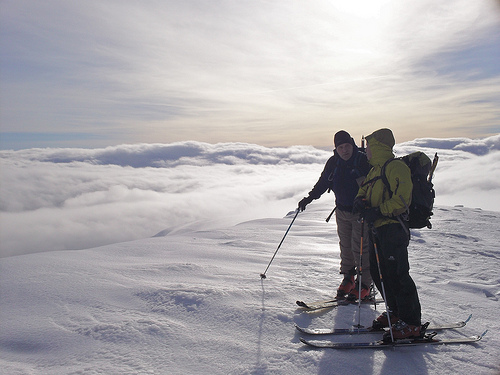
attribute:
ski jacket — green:
[312, 138, 344, 212]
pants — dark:
[366, 269, 419, 375]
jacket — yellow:
[384, 158, 417, 217]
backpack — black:
[421, 151, 432, 229]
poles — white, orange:
[334, 219, 451, 366]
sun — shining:
[288, 8, 399, 59]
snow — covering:
[40, 186, 386, 363]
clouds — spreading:
[26, 14, 396, 120]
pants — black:
[366, 237, 469, 349]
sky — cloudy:
[51, 38, 471, 158]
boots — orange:
[319, 265, 379, 295]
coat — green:
[355, 148, 419, 216]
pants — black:
[353, 232, 434, 313]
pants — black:
[380, 250, 461, 334]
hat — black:
[320, 131, 382, 177]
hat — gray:
[368, 123, 426, 144]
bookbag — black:
[405, 159, 461, 235]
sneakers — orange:
[308, 260, 385, 310]